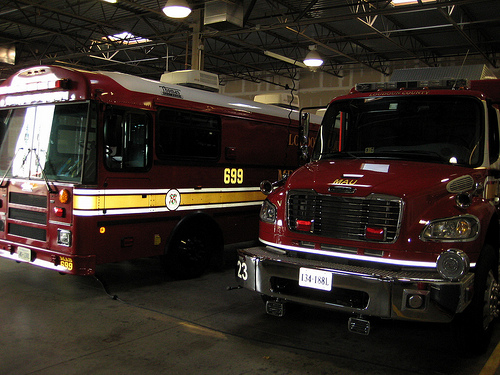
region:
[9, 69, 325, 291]
red and gold bus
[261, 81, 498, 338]
red fire truck in garage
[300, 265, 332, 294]
white and black license plate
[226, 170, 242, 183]
gold numbers on bus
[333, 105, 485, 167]
windshield on fire truck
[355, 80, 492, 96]
lights on truck roof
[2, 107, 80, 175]
wind shield on bus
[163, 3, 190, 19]
light attached to roof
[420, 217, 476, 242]
headlight on fire truck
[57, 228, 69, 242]
headlight on bus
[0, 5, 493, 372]
fire tracks on fire station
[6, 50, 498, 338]
two red trucks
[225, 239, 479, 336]
bumper of truck is color silver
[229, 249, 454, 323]
a plate over a bumper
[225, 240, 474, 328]
number 23 on left side of bumper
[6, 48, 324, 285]
truck has white roof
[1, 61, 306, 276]
number 699 on side of truck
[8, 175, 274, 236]
yellow and white lines on side of train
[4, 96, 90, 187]
wipes over a windshield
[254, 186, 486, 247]
headlights in front a red truck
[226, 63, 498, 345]
Fire truck parked in garage.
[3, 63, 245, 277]
Red truck parked in garage next to fire truck.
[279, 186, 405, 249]
Grill on front of fire truck.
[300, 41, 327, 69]
Light hanging from ceiling in garage.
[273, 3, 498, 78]
Steel girders supporting roof of garage.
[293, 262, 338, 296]
Tag on front of fire truck.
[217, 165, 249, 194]
Number painted in yellow on side of bus.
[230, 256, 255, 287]
Number painted in white on fire truck's bumper.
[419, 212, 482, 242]
Headlight on front of fire truck.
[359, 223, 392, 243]
Red flashing emergency light on front of fire truck.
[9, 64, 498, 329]
two dark red large vehicles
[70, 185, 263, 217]
yellow and white stripes running down side of bus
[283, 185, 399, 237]
front grill of truck cab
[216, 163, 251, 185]
699 in yellow on side of bus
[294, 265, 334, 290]
front white license plate of truck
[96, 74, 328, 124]
white top of bus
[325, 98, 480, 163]
front window of truck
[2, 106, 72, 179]
front window of bus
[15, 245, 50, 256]
license plate on front of bus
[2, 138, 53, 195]
windshield wipers on front of bus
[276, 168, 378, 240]
This is a fire engine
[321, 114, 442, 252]
This is a fire engine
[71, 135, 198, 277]
This is a fire engine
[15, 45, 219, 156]
This is a fire engine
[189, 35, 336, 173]
This is a fire engine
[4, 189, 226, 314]
This is a fire engine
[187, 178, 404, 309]
This is a fire engine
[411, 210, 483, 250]
This is head lamp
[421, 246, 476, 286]
This is head lamp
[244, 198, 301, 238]
This is head lamp